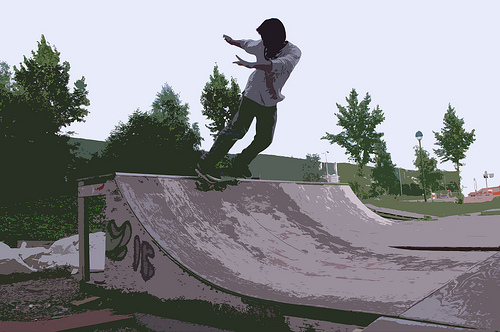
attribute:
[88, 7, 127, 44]
clouds — white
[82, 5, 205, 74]
sky — blue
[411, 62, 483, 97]
clouds — white 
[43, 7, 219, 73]
sky — blue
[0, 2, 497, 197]
clouds — white 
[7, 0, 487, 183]
sky — blue 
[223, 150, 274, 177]
shoe — skater's left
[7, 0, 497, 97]
clouds — white 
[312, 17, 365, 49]
clouds — white 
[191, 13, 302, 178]
man — young, skateboarding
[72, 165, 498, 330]
ramp — wood skateboard 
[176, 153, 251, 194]
right shoe — skater's right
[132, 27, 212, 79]
cloud — white 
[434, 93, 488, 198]
tree — tall green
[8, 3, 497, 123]
sky — blue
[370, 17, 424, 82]
clouds — white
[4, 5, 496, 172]
sky — blue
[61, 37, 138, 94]
cloud — white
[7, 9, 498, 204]
sky — blue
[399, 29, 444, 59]
clouds — white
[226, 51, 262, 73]
hand — skater's left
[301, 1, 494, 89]
clouds — white 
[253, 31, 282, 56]
face — skater's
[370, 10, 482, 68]
sky — blue 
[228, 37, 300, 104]
shirt — white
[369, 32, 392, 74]
clouds — white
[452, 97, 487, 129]
clouds — white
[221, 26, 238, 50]
hand — skater's hand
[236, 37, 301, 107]
shirt — white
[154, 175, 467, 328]
ramp —  skate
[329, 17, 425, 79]
clouds — white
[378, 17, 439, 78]
sky — blue 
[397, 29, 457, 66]
sky — blue 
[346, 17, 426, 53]
clouds — white 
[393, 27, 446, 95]
clouds — white 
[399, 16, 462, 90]
sky — blue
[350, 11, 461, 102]
clouds — white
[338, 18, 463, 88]
clouds — white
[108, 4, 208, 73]
sky — blue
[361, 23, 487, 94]
clouds — white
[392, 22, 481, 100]
clouds — white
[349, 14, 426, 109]
sky — blue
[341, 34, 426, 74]
clouds — white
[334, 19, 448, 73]
sky — blue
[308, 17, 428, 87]
clouds — white